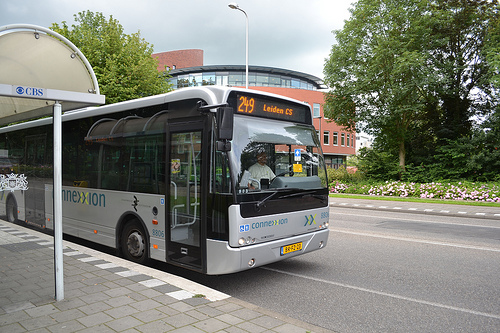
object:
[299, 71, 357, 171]
building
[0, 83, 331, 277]
bus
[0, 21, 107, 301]
bus stop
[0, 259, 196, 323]
sidewalk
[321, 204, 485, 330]
street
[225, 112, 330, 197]
windshield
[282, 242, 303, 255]
license plate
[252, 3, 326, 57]
sky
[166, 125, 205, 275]
door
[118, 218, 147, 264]
tire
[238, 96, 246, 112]
number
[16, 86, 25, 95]
lettes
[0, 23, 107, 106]
awning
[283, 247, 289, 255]
yellow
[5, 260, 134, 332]
bricks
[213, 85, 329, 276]
front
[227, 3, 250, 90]
pole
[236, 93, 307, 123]
display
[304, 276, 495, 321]
line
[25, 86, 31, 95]
letter c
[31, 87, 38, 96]
letter b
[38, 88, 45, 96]
letter s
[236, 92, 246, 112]
number 2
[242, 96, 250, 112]
number 4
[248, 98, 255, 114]
number 9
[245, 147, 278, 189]
driver